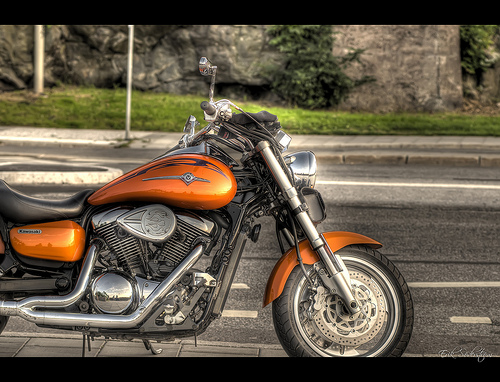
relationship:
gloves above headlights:
[231, 105, 282, 135] [285, 147, 320, 191]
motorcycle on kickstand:
[1, 47, 415, 358] [139, 336, 165, 355]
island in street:
[1, 152, 125, 191] [2, 138, 500, 360]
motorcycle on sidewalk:
[1, 47, 415, 358] [1, 327, 438, 357]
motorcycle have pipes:
[1, 47, 415, 358] [0, 240, 207, 334]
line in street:
[409, 272, 499, 293] [2, 138, 500, 360]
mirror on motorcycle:
[193, 57, 221, 102] [1, 47, 415, 358]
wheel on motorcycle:
[269, 243, 417, 356] [1, 47, 415, 358]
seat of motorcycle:
[0, 175, 94, 228] [1, 47, 415, 358]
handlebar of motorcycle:
[198, 98, 221, 124] [1, 47, 415, 358]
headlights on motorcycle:
[285, 147, 320, 191] [1, 47, 415, 358]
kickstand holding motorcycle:
[139, 336, 165, 355] [1, 47, 415, 358]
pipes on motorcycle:
[0, 240, 207, 334] [1, 47, 415, 358]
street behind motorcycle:
[5, 121, 490, 301] [1, 47, 415, 358]